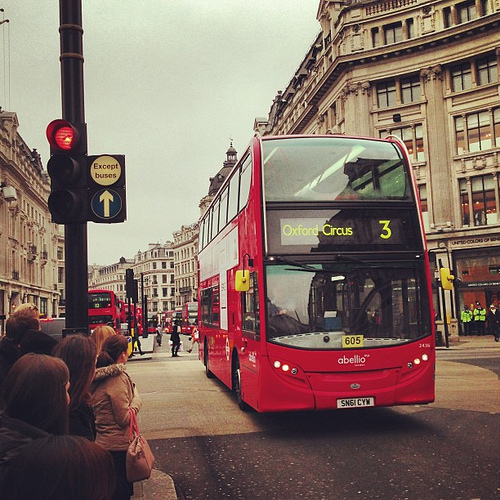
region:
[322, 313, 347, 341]
part of a window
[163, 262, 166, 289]
part of a building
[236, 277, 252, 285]
part of a side mirror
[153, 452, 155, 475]
part of bus stop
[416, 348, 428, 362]
part of a light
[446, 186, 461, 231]
part of a building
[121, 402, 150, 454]
part of a jacket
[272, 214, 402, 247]
the words are yellow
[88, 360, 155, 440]
the coat is brown in color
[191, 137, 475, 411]
the bus is a double decker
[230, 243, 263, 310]
the mirror is yellow with black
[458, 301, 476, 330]
the coat is neon green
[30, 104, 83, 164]
the light is red in color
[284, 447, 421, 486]
the road is black with white specks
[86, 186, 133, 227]
the sign is blue and white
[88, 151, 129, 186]
the sign is black and white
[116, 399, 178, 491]
the purse is tan with red handles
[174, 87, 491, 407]
the bus is red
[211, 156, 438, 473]
the bus is red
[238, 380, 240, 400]
part of a wheel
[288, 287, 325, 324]
part of a window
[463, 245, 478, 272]
part of a building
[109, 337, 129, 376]
head of a woman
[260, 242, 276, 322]
edge of a bus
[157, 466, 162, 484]
part of a bus stop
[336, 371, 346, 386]
bottom of a bus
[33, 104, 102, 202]
Traffic signal is on red light.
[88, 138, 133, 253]
Sign on side of black pole.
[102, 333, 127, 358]
Person has brown hair.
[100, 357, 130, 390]
Fur on person's coat.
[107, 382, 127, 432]
Person wearing tan coat.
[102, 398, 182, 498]
Person holding large bag.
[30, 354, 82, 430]
Person has brown hair.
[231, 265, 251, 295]
Yellow mirror on side of bus.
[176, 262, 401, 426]
Large red bus in road.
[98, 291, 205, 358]
Many red buses in background.